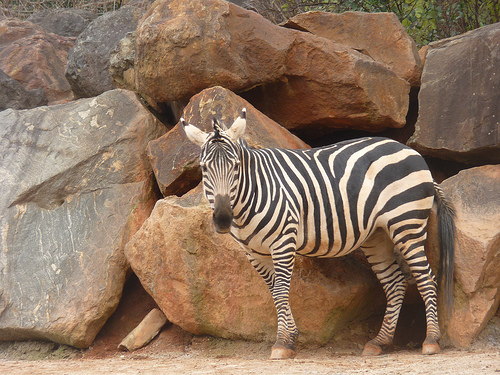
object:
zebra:
[180, 107, 458, 359]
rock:
[0, 87, 170, 350]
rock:
[106, 1, 412, 130]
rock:
[407, 23, 500, 160]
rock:
[146, 86, 314, 197]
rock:
[123, 178, 386, 347]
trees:
[232, 1, 498, 47]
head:
[177, 107, 249, 235]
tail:
[433, 180, 461, 321]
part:
[268, 251, 299, 362]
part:
[177, 115, 202, 148]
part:
[199, 179, 239, 237]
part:
[224, 101, 249, 142]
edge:
[295, 247, 361, 257]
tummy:
[296, 226, 375, 257]